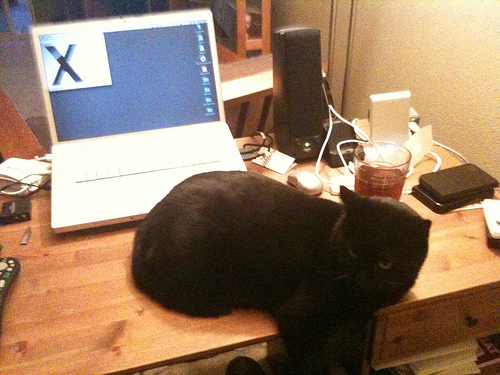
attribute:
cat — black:
[133, 170, 431, 373]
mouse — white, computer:
[284, 166, 324, 201]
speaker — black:
[258, 18, 358, 168]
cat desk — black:
[129, 158, 442, 358]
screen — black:
[36, 18, 221, 146]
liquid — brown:
[351, 167, 403, 193]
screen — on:
[30, 8, 226, 144]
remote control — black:
[0, 257, 22, 307]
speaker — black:
[264, 18, 334, 166]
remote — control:
[0, 255, 20, 315]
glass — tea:
[352, 140, 412, 198]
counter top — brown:
[1, 119, 496, 371]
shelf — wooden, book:
[189, 12, 333, 99]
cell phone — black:
[409, 159, 499, 216]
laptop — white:
[25, 7, 250, 236]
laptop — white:
[31, 11, 264, 219]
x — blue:
[47, 42, 81, 87]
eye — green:
[378, 257, 390, 268]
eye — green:
[345, 242, 361, 258]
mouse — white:
[283, 167, 323, 194]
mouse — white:
[268, 160, 338, 205]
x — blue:
[29, 28, 112, 94]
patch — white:
[38, 29, 113, 93]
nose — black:
[349, 268, 369, 283]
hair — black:
[370, 205, 404, 245]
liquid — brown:
[346, 158, 403, 202]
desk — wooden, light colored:
[3, 106, 476, 373]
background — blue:
[86, 31, 229, 132]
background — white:
[21, 28, 223, 127]